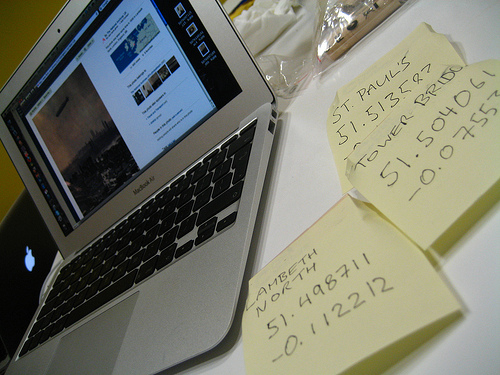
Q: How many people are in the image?
A: 0.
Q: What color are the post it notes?
A: Yellow.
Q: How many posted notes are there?
A: 3.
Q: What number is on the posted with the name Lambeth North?
A: 51.498711 -0.112212.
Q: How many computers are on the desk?
A: 2.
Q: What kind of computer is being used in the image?
A: Macbook.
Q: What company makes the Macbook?
A: Apple.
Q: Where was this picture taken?
A: At the desk.